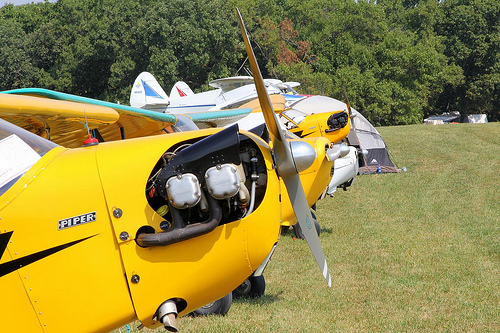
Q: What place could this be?
A: It is a field.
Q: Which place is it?
A: It is a field.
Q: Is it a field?
A: Yes, it is a field.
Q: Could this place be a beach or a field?
A: It is a field.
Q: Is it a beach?
A: No, it is a field.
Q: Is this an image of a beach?
A: No, the picture is showing a field.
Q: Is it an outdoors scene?
A: Yes, it is outdoors.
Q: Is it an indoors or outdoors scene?
A: It is outdoors.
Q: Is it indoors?
A: No, it is outdoors.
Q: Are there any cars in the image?
A: No, there are no cars.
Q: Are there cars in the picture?
A: No, there are no cars.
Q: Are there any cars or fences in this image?
A: No, there are no cars or fences.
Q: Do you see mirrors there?
A: No, there are no mirrors.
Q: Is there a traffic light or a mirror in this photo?
A: No, there are no mirrors or traffic lights.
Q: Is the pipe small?
A: Yes, the pipe is small.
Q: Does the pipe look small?
A: Yes, the pipe is small.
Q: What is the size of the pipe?
A: The pipe is small.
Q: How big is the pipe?
A: The pipe is small.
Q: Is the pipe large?
A: No, the pipe is small.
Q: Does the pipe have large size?
A: No, the pipe is small.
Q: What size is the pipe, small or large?
A: The pipe is small.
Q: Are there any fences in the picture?
A: No, there are no fences.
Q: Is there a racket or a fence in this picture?
A: No, there are no fences or rackets.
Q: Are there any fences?
A: No, there are no fences.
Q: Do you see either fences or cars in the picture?
A: No, there are no fences or cars.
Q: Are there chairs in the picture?
A: No, there are no chairs.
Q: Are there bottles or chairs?
A: No, there are no chairs or bottles.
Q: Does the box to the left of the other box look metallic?
A: Yes, the box is metallic.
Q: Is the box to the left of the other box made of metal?
A: Yes, the box is made of metal.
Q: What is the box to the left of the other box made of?
A: The box is made of metal.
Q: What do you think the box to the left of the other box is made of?
A: The box is made of metal.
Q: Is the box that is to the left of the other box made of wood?
A: No, the box is made of metal.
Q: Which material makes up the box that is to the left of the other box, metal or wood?
A: The box is made of metal.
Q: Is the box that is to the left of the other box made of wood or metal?
A: The box is made of metal.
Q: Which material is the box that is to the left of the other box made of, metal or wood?
A: The box is made of metal.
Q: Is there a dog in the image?
A: No, there are no dogs.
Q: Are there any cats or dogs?
A: No, there are no dogs or cats.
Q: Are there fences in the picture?
A: No, there are no fences.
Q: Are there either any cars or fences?
A: No, there are no fences or cars.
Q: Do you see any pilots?
A: No, there are no pilots.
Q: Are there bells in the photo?
A: No, there are no bells.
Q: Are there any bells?
A: No, there are no bells.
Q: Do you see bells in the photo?
A: No, there are no bells.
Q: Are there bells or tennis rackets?
A: No, there are no bells or tennis rackets.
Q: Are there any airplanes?
A: Yes, there is an airplane.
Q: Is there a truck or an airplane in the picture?
A: Yes, there is an airplane.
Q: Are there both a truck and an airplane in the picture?
A: No, there is an airplane but no trucks.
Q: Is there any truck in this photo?
A: No, there are no trucks.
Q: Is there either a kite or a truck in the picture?
A: No, there are no trucks or kites.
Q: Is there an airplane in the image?
A: Yes, there is an airplane.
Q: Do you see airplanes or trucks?
A: Yes, there is an airplane.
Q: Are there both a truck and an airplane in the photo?
A: No, there is an airplane but no trucks.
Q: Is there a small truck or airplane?
A: Yes, there is a small airplane.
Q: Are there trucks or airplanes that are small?
A: Yes, the airplane is small.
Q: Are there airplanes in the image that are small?
A: Yes, there is a small airplane.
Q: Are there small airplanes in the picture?
A: Yes, there is a small airplane.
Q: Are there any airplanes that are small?
A: Yes, there is a small airplane.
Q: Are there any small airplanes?
A: Yes, there is a small airplane.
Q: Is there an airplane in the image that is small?
A: Yes, there is an airplane that is small.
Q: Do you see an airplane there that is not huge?
A: Yes, there is a small airplane.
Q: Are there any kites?
A: No, there are no kites.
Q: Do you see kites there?
A: No, there are no kites.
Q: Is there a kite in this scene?
A: No, there are no kites.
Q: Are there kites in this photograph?
A: No, there are no kites.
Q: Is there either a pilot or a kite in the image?
A: No, there are no kites or pilots.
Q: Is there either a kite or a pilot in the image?
A: No, there are no kites or pilots.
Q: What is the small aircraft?
A: The aircraft is an airplane.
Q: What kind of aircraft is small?
A: The aircraft is an airplane.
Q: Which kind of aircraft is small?
A: The aircraft is an airplane.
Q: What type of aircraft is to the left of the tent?
A: The aircraft is an airplane.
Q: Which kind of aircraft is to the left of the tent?
A: The aircraft is an airplane.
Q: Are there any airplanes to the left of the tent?
A: Yes, there is an airplane to the left of the tent.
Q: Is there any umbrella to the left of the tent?
A: No, there is an airplane to the left of the tent.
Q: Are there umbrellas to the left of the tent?
A: No, there is an airplane to the left of the tent.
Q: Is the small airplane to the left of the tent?
A: Yes, the airplane is to the left of the tent.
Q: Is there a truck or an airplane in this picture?
A: Yes, there is an airplane.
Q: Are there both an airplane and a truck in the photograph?
A: No, there is an airplane but no trucks.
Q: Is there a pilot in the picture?
A: No, there are no pilots.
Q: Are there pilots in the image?
A: No, there are no pilots.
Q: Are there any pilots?
A: No, there are no pilots.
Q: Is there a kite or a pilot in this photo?
A: No, there are no pilots or kites.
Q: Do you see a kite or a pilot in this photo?
A: No, there are no pilots or kites.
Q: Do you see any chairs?
A: No, there are no chairs.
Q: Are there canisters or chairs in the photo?
A: No, there are no chairs or canisters.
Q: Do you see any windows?
A: Yes, there is a window.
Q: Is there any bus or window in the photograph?
A: Yes, there is a window.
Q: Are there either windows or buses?
A: Yes, there is a window.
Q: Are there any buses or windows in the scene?
A: Yes, there is a window.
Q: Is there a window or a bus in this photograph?
A: Yes, there is a window.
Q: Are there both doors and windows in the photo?
A: No, there is a window but no doors.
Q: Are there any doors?
A: No, there are no doors.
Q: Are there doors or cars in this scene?
A: No, there are no doors or cars.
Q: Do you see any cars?
A: No, there are no cars.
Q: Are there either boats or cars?
A: No, there are no cars or boats.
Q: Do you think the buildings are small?
A: Yes, the buildings are small.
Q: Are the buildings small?
A: Yes, the buildings are small.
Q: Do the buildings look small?
A: Yes, the buildings are small.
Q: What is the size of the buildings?
A: The buildings are small.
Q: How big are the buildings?
A: The buildings are small.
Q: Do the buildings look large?
A: No, the buildings are small.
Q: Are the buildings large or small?
A: The buildings are small.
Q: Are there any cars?
A: No, there are no cars.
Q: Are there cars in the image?
A: No, there are no cars.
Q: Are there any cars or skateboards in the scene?
A: No, there are no cars or skateboards.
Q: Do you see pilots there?
A: No, there are no pilots.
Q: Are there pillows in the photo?
A: No, there are no pillows.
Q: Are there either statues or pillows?
A: No, there are no pillows or statues.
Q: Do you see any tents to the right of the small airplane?
A: Yes, there is a tent to the right of the airplane.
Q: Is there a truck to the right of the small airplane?
A: No, there is a tent to the right of the plane.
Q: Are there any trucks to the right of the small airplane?
A: No, there is a tent to the right of the plane.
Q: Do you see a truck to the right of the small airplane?
A: No, there is a tent to the right of the plane.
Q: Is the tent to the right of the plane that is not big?
A: Yes, the tent is to the right of the airplane.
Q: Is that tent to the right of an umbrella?
A: No, the tent is to the right of the airplane.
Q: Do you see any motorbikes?
A: No, there are no motorbikes.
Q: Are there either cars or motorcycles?
A: No, there are no motorcycles or cars.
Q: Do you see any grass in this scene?
A: Yes, there is grass.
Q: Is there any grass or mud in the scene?
A: Yes, there is grass.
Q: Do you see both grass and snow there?
A: No, there is grass but no snow.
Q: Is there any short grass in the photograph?
A: Yes, there is short grass.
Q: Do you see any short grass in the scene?
A: Yes, there is short grass.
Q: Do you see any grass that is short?
A: Yes, there is grass that is short.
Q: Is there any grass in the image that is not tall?
A: Yes, there is short grass.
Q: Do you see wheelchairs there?
A: No, there are no wheelchairs.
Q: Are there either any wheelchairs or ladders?
A: No, there are no wheelchairs or ladders.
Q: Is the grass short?
A: Yes, the grass is short.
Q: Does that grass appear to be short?
A: Yes, the grass is short.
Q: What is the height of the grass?
A: The grass is short.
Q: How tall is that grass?
A: The grass is short.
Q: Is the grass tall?
A: No, the grass is short.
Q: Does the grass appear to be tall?
A: No, the grass is short.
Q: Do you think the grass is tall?
A: No, the grass is short.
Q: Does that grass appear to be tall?
A: No, the grass is short.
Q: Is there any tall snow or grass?
A: No, there is grass but it is short.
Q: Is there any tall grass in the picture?
A: No, there is grass but it is short.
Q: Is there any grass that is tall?
A: No, there is grass but it is short.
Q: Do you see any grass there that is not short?
A: No, there is grass but it is short.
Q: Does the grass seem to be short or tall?
A: The grass is short.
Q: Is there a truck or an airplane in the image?
A: Yes, there is an airplane.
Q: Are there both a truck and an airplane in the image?
A: No, there is an airplane but no trucks.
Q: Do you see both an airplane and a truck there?
A: No, there is an airplane but no trucks.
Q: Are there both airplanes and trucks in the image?
A: No, there is an airplane but no trucks.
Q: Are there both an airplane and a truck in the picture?
A: No, there is an airplane but no trucks.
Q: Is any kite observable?
A: No, there are no kites.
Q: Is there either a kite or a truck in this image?
A: No, there are no kites or trucks.